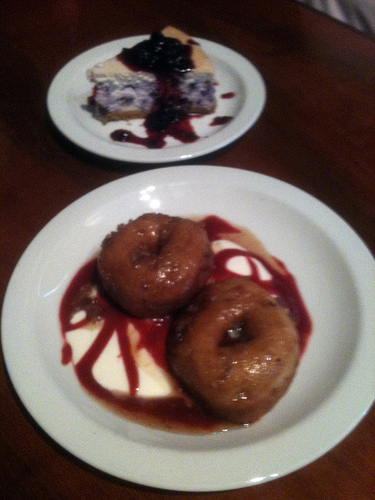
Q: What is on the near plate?
A: Donuts with sauce.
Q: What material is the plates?
A: Ceramic.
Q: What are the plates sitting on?
A: A table.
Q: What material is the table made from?
A: Wood.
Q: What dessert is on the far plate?
A: Pie.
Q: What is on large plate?
A: Doughnuts.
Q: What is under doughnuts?
A: Red sauce.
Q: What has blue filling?
A: The pie.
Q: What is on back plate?
A: Piece of cake.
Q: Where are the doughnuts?
A: Round plate.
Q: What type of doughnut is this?
A: Cake doughnut.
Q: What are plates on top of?
A: Brown table.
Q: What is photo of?
A: Desserts.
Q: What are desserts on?
A: White plates.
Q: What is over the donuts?
A: Red sauce.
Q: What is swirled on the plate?
A: Red icing.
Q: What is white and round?
A: Plate.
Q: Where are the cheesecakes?
A: On the plate.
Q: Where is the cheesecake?
A: On the plate.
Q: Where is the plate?
A: On the table.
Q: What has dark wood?
A: Table.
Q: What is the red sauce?
A: Thick.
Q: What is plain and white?
A: Plate.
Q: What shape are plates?
A: Round.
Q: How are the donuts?
A: Glazed.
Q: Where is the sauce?
A: Under donuts.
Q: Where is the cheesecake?
A: On plate.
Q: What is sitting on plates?
A: Desserts.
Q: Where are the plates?
A: On table.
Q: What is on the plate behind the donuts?
A: A cheesecake.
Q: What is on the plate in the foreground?
A: Two donuts.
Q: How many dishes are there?
A: Two.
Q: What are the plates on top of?
A: A table.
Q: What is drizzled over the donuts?
A: A sauce.